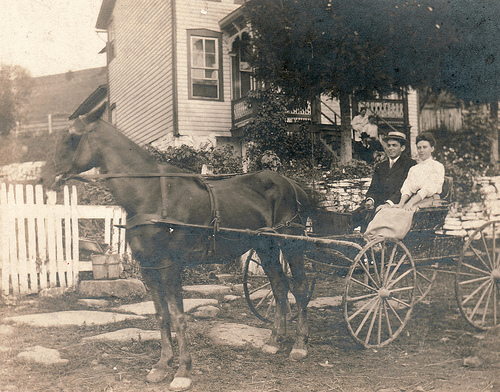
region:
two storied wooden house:
[100, 0, 420, 167]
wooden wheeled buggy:
[242, 179, 499, 349]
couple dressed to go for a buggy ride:
[330, 130, 457, 254]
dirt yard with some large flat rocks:
[4, 275, 496, 388]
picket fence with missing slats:
[0, 190, 133, 287]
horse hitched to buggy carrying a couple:
[40, 107, 335, 388]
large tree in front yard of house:
[240, 3, 497, 154]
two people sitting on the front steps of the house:
[345, 107, 381, 149]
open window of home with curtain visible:
[190, 32, 221, 99]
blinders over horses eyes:
[62, 130, 84, 148]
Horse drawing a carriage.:
[37, 96, 309, 386]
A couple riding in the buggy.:
[361, 120, 462, 208]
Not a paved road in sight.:
[318, 341, 441, 385]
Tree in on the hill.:
[0, 57, 48, 136]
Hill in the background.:
[16, 58, 103, 134]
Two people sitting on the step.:
[344, 103, 386, 141]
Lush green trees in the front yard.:
[301, 43, 491, 103]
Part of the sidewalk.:
[19, 305, 131, 335]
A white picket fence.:
[1, 185, 88, 304]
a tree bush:
[273, 10, 420, 65]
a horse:
[46, 96, 319, 386]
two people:
[379, 128, 442, 200]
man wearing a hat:
[385, 128, 402, 140]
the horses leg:
[144, 283, 206, 389]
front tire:
[345, 247, 423, 348]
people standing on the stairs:
[351, 106, 381, 140]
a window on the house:
[192, 40, 218, 81]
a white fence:
[5, 185, 85, 293]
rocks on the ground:
[36, 303, 133, 330]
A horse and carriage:
[35, 95, 498, 389]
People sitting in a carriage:
[316, 125, 457, 263]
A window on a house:
[184, 21, 225, 106]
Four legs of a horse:
[139, 246, 317, 389]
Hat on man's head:
[380, 127, 410, 161]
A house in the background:
[92, 0, 408, 151]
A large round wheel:
[340, 236, 419, 352]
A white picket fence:
[3, 181, 132, 296]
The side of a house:
[104, 0, 176, 145]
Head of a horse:
[36, 96, 116, 200]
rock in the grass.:
[33, 340, 58, 355]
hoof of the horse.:
[171, 373, 194, 387]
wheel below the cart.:
[355, 263, 397, 322]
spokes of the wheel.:
[467, 263, 475, 299]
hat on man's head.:
[384, 125, 410, 138]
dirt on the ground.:
[391, 353, 434, 380]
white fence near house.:
[12, 200, 40, 269]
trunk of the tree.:
[336, 98, 352, 166]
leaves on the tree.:
[328, 43, 377, 77]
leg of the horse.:
[277, 259, 292, 348]